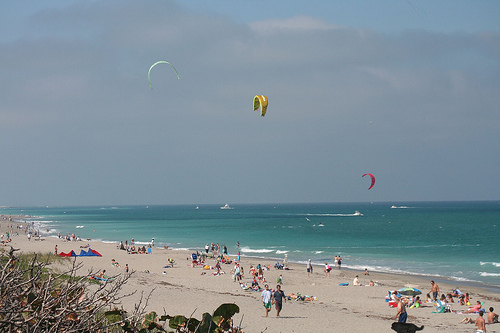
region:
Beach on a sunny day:
[4, 7, 498, 329]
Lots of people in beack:
[1, 230, 494, 330]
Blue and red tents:
[56, 243, 106, 259]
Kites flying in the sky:
[226, 80, 396, 213]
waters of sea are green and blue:
[10, 191, 496, 301]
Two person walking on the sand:
[255, 275, 288, 320]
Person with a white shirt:
[251, 280, 274, 317]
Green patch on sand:
[1, 240, 78, 271]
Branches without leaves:
[6, 246, 173, 329]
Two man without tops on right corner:
[470, 304, 498, 331]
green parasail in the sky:
[137, 40, 216, 145]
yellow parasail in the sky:
[242, 67, 312, 149]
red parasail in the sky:
[339, 127, 404, 229]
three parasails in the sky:
[130, 30, 435, 246]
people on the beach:
[0, 200, 499, 332]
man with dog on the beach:
[383, 291, 425, 331]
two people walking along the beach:
[240, 277, 317, 324]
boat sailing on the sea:
[207, 192, 275, 214]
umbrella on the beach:
[395, 272, 442, 316]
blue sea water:
[42, 199, 499, 286]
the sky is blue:
[0, 0, 498, 208]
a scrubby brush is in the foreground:
[1, 246, 241, 329]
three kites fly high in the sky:
[141, 50, 377, 192]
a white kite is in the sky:
[139, 51, 183, 92]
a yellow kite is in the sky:
[253, 87, 270, 122]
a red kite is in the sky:
[358, 170, 378, 192]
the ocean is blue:
[3, 199, 499, 289]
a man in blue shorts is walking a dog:
[388, 292, 423, 331]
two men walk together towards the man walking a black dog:
[259, 281, 288, 318]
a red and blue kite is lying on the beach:
[57, 245, 104, 258]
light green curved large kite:
[146, 57, 178, 89]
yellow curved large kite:
[251, 94, 270, 114]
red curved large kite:
[362, 172, 377, 193]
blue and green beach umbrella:
[398, 287, 421, 297]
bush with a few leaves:
[0, 249, 240, 331]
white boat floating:
[220, 201, 232, 213]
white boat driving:
[352, 208, 360, 219]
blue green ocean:
[8, 203, 498, 286]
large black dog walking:
[391, 320, 421, 332]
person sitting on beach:
[351, 274, 362, 286]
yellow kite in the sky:
[230, 93, 274, 120]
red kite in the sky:
[364, 162, 379, 189]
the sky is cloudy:
[63, 127, 287, 170]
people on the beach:
[214, 241, 283, 301]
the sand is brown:
[181, 275, 236, 300]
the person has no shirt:
[474, 316, 489, 327]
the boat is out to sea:
[209, 201, 240, 212]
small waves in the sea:
[238, 244, 276, 257]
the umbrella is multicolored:
[397, 280, 425, 300]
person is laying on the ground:
[453, 308, 475, 331]